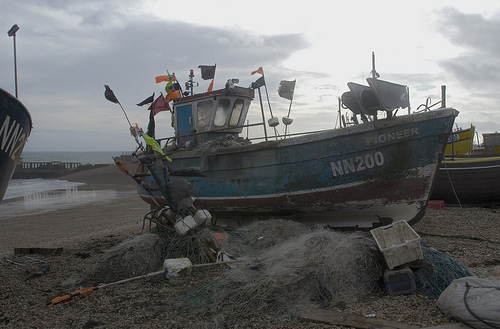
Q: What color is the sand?
A: Brown.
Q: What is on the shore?
A: Boats.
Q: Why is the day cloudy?
A: It will rain.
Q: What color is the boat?
A: Blue.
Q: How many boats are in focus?
A: One.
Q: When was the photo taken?
A: Evening.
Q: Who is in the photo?
A: No one.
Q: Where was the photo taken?
A: At the beach.